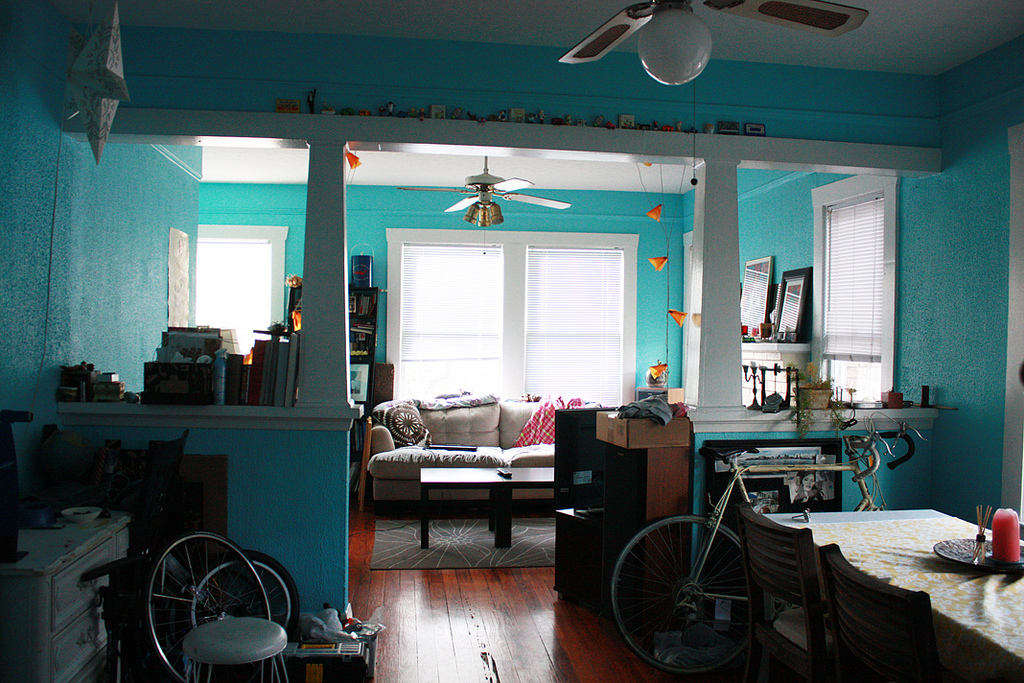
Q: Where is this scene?
A: In a living room.